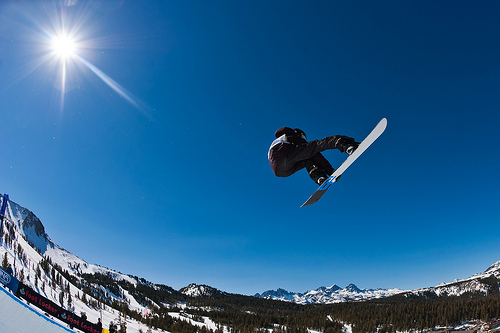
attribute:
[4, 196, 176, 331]
slope — snow covered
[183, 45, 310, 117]
sky — blue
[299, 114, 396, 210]
snowboard — white, blue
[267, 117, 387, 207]
skater — air born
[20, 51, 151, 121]
rays — sun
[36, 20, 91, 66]
sun — bright 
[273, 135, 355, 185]
pants — dark